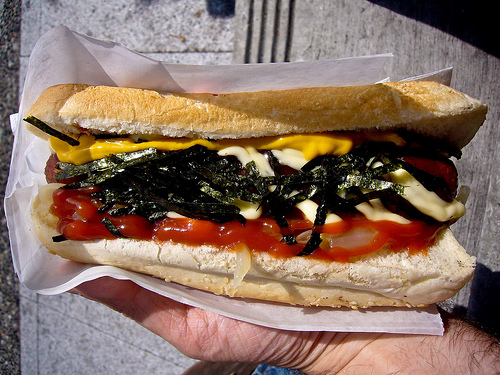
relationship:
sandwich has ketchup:
[25, 86, 487, 256] [55, 192, 426, 260]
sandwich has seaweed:
[25, 86, 487, 256] [20, 114, 417, 258]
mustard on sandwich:
[52, 130, 353, 165] [25, 86, 487, 256]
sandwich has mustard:
[25, 86, 487, 256] [52, 130, 353, 165]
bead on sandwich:
[221, 145, 305, 174] [25, 86, 487, 256]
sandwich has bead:
[25, 86, 487, 256] [221, 145, 305, 174]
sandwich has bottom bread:
[25, 86, 487, 256] [41, 232, 480, 317]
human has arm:
[83, 278, 500, 375] [311, 320, 498, 374]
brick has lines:
[21, 1, 498, 265] [245, 0, 295, 66]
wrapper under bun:
[4, 27, 452, 338] [28, 81, 489, 153]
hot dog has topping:
[358, 144, 459, 218] [241, 170, 465, 229]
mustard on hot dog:
[52, 130, 353, 165] [358, 144, 459, 218]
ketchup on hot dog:
[55, 192, 426, 260] [358, 144, 459, 218]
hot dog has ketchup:
[358, 144, 459, 218] [55, 192, 426, 260]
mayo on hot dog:
[352, 174, 459, 237] [358, 144, 459, 218]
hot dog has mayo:
[358, 144, 459, 218] [352, 174, 459, 237]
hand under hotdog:
[61, 266, 347, 362] [25, 86, 487, 256]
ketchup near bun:
[55, 192, 426, 260] [28, 81, 489, 153]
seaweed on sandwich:
[21, 116, 413, 249] [25, 86, 487, 256]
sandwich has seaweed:
[25, 86, 487, 256] [21, 116, 413, 249]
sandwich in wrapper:
[25, 86, 487, 256] [4, 27, 452, 338]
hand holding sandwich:
[61, 266, 347, 362] [25, 86, 487, 256]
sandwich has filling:
[25, 86, 487, 256] [45, 131, 467, 261]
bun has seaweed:
[28, 81, 489, 153] [21, 116, 413, 249]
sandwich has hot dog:
[25, 86, 487, 256] [358, 144, 459, 218]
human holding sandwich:
[83, 278, 500, 375] [25, 86, 487, 256]